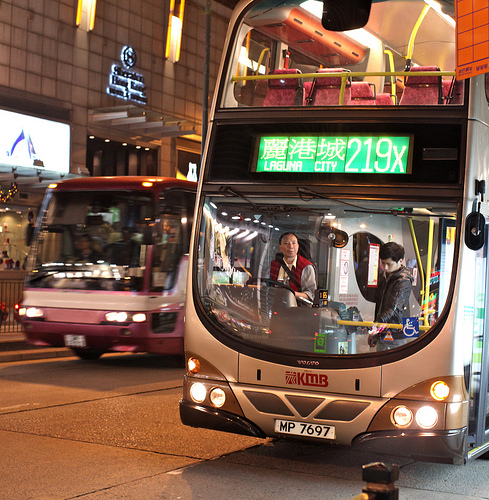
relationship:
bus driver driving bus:
[257, 222, 319, 307] [174, 0, 488, 469]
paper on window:
[367, 242, 380, 288] [352, 229, 387, 303]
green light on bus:
[253, 128, 417, 176] [171, 0, 483, 466]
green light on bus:
[253, 128, 417, 176] [14, 162, 215, 363]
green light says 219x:
[251, 128, 418, 176] [340, 128, 408, 172]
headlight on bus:
[386, 400, 414, 433] [179, 0, 487, 426]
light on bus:
[416, 403, 442, 426] [179, 0, 487, 426]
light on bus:
[431, 378, 455, 401] [179, 0, 487, 426]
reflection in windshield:
[198, 198, 267, 339] [190, 191, 463, 357]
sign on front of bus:
[263, 116, 486, 190] [173, 50, 478, 466]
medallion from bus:
[298, 355, 325, 368] [174, 0, 488, 469]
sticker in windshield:
[393, 310, 450, 340] [184, 200, 477, 343]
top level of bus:
[210, 0, 476, 108] [174, 0, 488, 469]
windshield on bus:
[204, 216, 449, 351] [29, 152, 202, 418]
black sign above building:
[105, 43, 148, 105] [0, 0, 234, 322]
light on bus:
[412, 403, 442, 432] [179, 0, 487, 426]